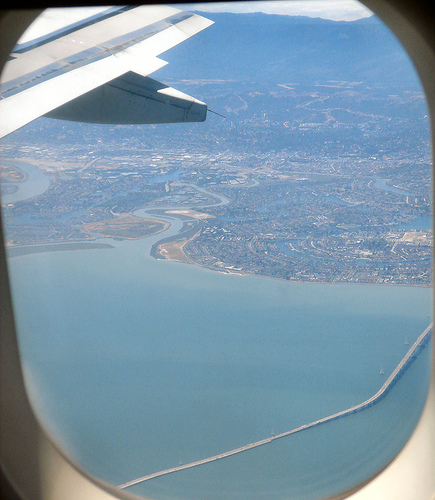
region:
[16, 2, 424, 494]
view from an airplane window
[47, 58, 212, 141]
engine on the wing of an airplane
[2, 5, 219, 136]
gray and white partial wing of an airplane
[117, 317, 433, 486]
bridge over blue water looking out an airplane window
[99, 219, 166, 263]
mouth of a river as seen from an airplane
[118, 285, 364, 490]
blue water as seen out the window of an airplane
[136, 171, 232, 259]
a river as seen out the window of an airplane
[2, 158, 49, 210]
portion of a river as seen out an airplane window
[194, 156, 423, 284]
suburban area with many homes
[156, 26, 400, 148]
rural area as seen from the window of an airplane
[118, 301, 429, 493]
Aerial view of bridge water crossing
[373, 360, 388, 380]
Channel buoy in water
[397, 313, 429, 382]
Elevated part of bridge to allow boat traffic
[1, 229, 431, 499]
Interior of airplane window frame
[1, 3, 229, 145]
Wingtip of airplane in flight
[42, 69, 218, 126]
Wing flap mechanism housing on airplane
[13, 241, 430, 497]
Large body of water below airplane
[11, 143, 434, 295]
Aerial view of coastline city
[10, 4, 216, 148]
Wing flap being deployed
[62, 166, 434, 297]
River delta area of city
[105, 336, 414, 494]
a long bridge crossing a large body of water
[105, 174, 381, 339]
a view of land from a air plane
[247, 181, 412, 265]
several bodies of water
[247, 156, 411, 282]
several bodies of water surrounded by land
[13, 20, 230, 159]
a wing of a airplane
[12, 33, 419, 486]
the round window in a airplane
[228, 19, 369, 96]
mountains covered with trees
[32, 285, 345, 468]
a large body of blue water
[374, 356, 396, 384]
a boat in the water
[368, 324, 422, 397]
two boats in the water next to a bridge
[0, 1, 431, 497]
the frame of an airplane window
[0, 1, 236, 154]
the wing of an airplane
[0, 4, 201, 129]
the wing flap is lifted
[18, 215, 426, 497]
a large river under the plane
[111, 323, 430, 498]
a bridge across the river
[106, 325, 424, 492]
the bridge is long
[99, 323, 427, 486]
the bridge is turned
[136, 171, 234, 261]
a small river flowing from the large river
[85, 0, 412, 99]
mountains behind the city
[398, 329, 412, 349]
a boat beside the bridge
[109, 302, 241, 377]
this is the water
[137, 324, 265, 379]
the water is blue in color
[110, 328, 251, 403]
the water is calm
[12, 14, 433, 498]
this is a window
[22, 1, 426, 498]
the window is big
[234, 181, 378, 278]
these are some buildings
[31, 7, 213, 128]
this is a wing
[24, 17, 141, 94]
the wing is big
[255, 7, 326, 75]
this is a mountain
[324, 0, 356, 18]
this is the sky